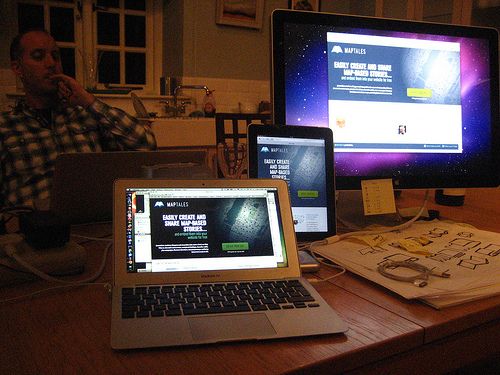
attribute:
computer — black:
[263, 69, 499, 201]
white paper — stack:
[310, 220, 484, 308]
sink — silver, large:
[162, 80, 208, 120]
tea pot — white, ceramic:
[236, 100, 256, 113]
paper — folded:
[364, 238, 482, 249]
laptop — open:
[117, 177, 342, 350]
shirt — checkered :
[19, 135, 49, 169]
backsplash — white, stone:
[214, 85, 251, 105]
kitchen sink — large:
[157, 77, 219, 147]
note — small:
[358, 171, 398, 215]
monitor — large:
[271, 12, 479, 171]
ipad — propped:
[251, 123, 343, 237]